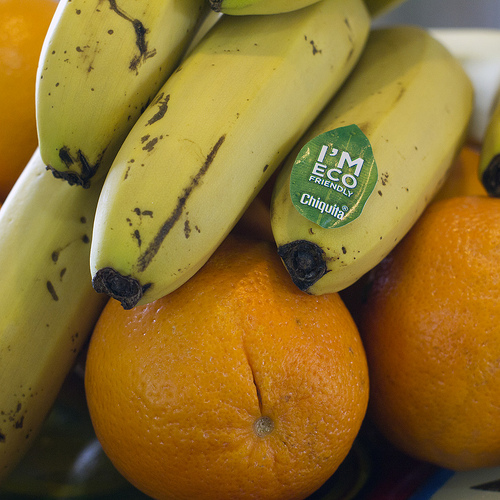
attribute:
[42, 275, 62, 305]
spot — brown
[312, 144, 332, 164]
i — white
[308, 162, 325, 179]
letter — white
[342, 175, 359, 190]
letter — white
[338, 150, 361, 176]
letter — white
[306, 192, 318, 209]
letter h — white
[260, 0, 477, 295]
bananas — yellow, bunch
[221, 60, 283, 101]
skin — banana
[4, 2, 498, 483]
fruit — orange, yellow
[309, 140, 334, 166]
letter i — white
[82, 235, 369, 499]
fruit — unpeeled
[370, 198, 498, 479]
fruit — unpeeled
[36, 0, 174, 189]
fruit — unpeeled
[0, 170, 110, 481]
fruit — unpeeled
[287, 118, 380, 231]
sticker — eco friendly, peeling, green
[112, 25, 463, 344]
banana — eco friendly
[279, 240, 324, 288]
end — blackened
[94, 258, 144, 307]
end — blackened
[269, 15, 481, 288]
banana — yellow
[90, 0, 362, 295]
banana — yellow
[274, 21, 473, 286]
fruit — unpeeled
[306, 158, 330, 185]
e — white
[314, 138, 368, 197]
lettering — white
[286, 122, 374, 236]
sticker — green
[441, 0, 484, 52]
background — white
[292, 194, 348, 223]
lettering — white